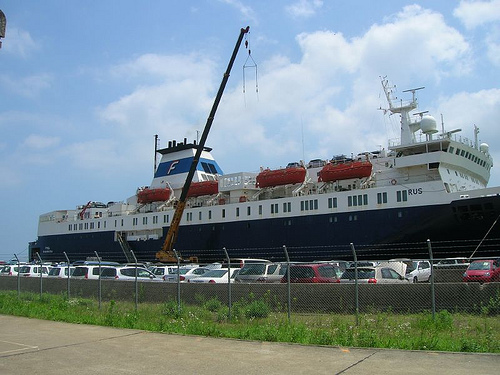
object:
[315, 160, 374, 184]
rafts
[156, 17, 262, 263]
crane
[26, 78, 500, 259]
ship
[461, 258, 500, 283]
cars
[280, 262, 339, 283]
car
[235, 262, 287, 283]
car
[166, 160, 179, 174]
letter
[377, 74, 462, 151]
radio equipment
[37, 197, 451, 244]
balcony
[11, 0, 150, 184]
sky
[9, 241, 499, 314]
fence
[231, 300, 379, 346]
grass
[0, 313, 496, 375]
ground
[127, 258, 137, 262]
stairs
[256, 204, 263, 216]
windows